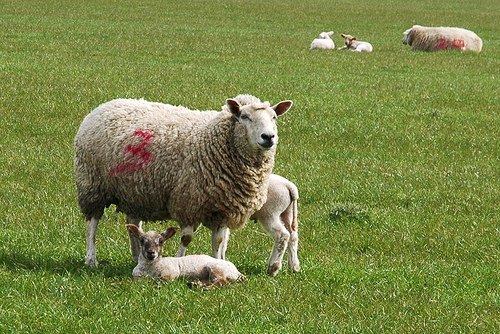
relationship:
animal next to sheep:
[223, 174, 301, 277] [68, 91, 293, 267]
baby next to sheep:
[124, 223, 248, 290] [68, 91, 293, 267]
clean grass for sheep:
[327, 75, 487, 319] [69, 89, 305, 296]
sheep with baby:
[68, 91, 293, 267] [130, 226, 190, 274]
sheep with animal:
[68, 91, 293, 267] [223, 174, 301, 277]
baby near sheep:
[124, 223, 248, 290] [70, 110, 262, 199]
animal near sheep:
[223, 174, 301, 277] [70, 110, 262, 199]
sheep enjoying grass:
[68, 91, 293, 267] [2, 5, 498, 327]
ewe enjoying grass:
[400, 24, 483, 53] [2, 5, 498, 327]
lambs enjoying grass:
[336, 33, 373, 53] [2, 5, 498, 327]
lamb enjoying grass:
[308, 31, 336, 51] [2, 5, 498, 327]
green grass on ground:
[0, 0, 498, 330] [306, 91, 471, 298]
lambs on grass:
[316, 9, 398, 56] [296, 76, 441, 240]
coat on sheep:
[72, 92, 277, 229] [68, 91, 293, 267]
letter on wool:
[107, 128, 154, 178] [57, 100, 219, 190]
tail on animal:
[288, 186, 300, 231] [223, 169, 303, 278]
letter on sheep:
[103, 124, 179, 185] [75, 103, 264, 239]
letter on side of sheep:
[107, 128, 154, 178] [71, 81, 281, 226]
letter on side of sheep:
[107, 128, 154, 178] [59, 74, 297, 278]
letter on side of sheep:
[432, 33, 469, 57] [401, 19, 483, 55]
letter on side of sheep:
[325, 201, 351, 224] [88, 110, 245, 220]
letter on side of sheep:
[107, 128, 154, 178] [68, 91, 293, 267]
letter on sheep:
[107, 128, 154, 178] [68, 91, 293, 267]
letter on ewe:
[432, 33, 464, 49] [400, 22, 483, 53]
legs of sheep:
[72, 211, 272, 263] [59, 47, 270, 245]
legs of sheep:
[175, 219, 233, 261] [114, 104, 296, 245]